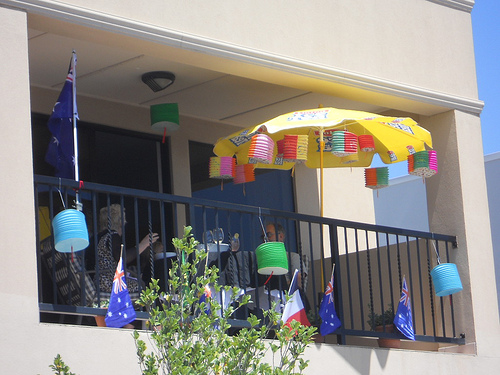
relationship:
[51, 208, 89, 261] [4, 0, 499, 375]
decoration hangs from balcony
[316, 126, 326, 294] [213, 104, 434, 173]
shaft of umbrella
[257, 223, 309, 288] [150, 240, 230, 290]
person sitting at table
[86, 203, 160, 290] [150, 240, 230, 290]
person sitting at table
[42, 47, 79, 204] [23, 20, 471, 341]
flag on balcony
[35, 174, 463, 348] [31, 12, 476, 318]
rail on balcony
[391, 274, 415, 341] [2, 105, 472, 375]
flags on a balcony